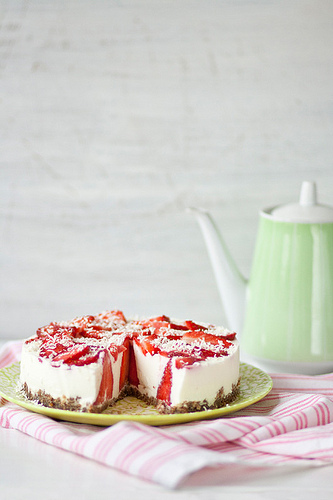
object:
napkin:
[0, 336, 333, 487]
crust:
[157, 401, 210, 412]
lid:
[261, 170, 331, 228]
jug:
[185, 177, 332, 385]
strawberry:
[155, 360, 174, 404]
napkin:
[2, 368, 332, 492]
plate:
[0, 358, 272, 425]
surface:
[191, 366, 228, 398]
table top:
[6, 443, 48, 496]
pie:
[18, 308, 247, 415]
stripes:
[289, 413, 302, 433]